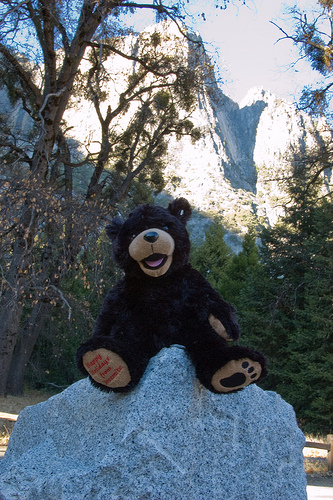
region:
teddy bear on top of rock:
[79, 195, 266, 392]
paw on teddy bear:
[220, 362, 257, 390]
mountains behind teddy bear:
[2, 17, 332, 253]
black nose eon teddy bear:
[144, 231, 160, 243]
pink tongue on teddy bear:
[143, 255, 162, 266]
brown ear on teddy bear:
[168, 197, 191, 223]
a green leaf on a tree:
[247, 281, 255, 291]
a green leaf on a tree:
[313, 392, 324, 399]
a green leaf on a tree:
[277, 373, 290, 382]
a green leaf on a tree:
[272, 333, 281, 341]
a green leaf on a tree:
[317, 339, 331, 349]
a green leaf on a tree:
[286, 344, 290, 355]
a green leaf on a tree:
[274, 383, 287, 388]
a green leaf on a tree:
[316, 391, 321, 400]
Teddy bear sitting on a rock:
[63, 192, 266, 397]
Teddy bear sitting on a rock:
[77, 195, 267, 401]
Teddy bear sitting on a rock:
[68, 190, 267, 405]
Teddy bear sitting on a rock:
[80, 186, 286, 417]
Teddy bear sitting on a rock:
[77, 191, 272, 403]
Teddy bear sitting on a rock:
[77, 198, 277, 407]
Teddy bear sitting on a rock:
[60, 189, 289, 410]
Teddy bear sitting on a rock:
[69, 187, 279, 396]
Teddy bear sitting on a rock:
[68, 179, 278, 403]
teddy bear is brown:
[70, 188, 255, 422]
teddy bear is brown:
[74, 198, 280, 426]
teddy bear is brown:
[71, 194, 282, 432]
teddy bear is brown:
[66, 201, 262, 412]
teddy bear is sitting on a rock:
[58, 183, 281, 493]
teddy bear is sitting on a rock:
[57, 179, 272, 494]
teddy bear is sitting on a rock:
[68, 201, 306, 484]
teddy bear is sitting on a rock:
[80, 192, 299, 475]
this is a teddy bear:
[61, 180, 279, 400]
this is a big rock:
[4, 352, 310, 493]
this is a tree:
[202, 212, 235, 296]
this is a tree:
[218, 221, 277, 364]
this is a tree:
[0, 0, 133, 386]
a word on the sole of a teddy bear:
[84, 356, 106, 369]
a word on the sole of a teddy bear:
[100, 365, 129, 388]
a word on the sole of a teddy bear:
[96, 366, 115, 379]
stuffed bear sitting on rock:
[72, 195, 266, 399]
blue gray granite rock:
[3, 339, 315, 498]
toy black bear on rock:
[68, 194, 270, 400]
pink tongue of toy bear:
[139, 254, 165, 270]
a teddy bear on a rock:
[46, 187, 271, 436]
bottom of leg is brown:
[75, 345, 134, 393]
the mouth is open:
[136, 245, 171, 276]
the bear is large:
[69, 188, 272, 404]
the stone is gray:
[0, 342, 313, 499]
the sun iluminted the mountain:
[7, 8, 321, 243]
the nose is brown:
[138, 228, 161, 246]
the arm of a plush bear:
[188, 272, 242, 344]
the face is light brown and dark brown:
[98, 195, 196, 282]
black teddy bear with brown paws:
[75, 197, 266, 391]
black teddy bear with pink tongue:
[76, 197, 264, 397]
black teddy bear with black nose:
[74, 197, 268, 394]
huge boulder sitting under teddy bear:
[0, 347, 305, 495]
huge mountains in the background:
[1, 49, 331, 245]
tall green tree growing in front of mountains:
[275, 266, 331, 426]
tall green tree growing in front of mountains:
[222, 225, 279, 376]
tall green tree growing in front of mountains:
[193, 219, 232, 290]